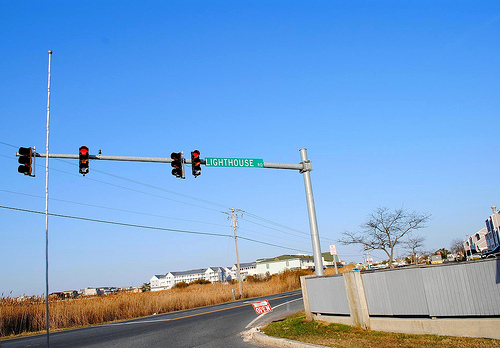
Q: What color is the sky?
A: Blue.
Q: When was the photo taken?
A: Daytime.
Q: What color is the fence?
A: Silver.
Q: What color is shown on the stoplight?
A: Red.